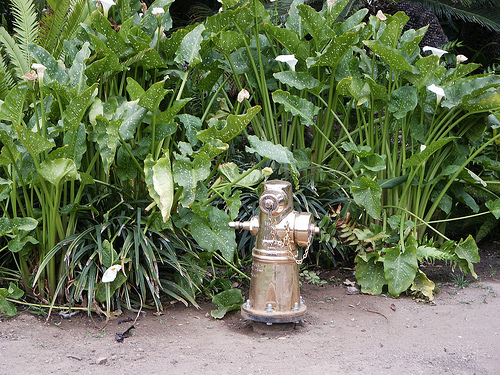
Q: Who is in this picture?
A: No one.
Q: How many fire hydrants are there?
A: One.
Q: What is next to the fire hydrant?
A: Plants.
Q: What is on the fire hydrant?
A: A chain.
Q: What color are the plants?
A: Green.